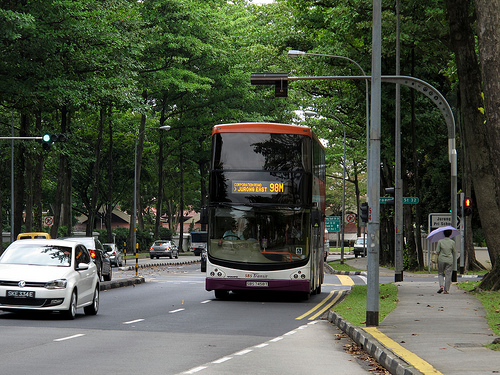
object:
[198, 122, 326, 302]
bus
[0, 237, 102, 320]
car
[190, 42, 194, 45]
leaves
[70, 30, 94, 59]
green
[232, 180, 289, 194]
sign